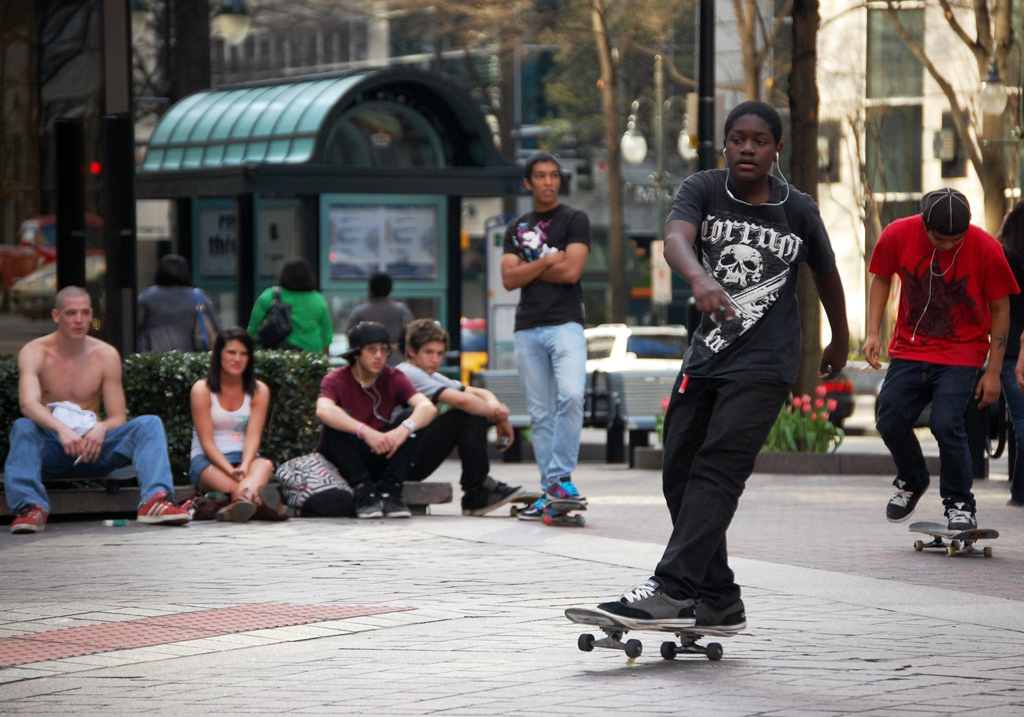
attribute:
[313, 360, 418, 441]
shirt — maroon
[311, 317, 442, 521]
man — maroon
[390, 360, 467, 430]
shirt — blue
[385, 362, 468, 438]
shirt — blue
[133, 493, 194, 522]
shoes — red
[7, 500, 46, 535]
shoes — red